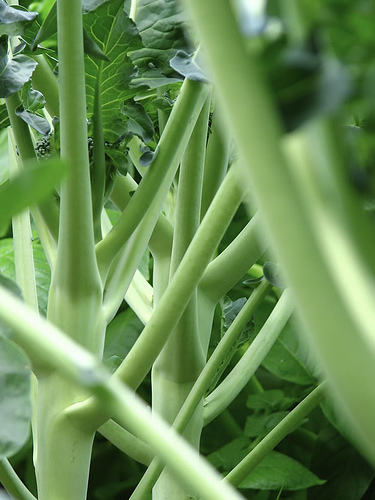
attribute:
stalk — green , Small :
[163, 90, 216, 303]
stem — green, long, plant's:
[78, 162, 246, 429]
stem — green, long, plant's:
[208, 211, 273, 299]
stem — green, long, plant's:
[0, 284, 248, 498]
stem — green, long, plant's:
[0, 93, 55, 247]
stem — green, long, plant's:
[222, 375, 332, 484]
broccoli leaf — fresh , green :
[72, 0, 140, 156]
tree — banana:
[1, 1, 372, 497]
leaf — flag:
[81, 0, 145, 145]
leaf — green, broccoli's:
[85, 13, 138, 125]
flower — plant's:
[66, 21, 289, 233]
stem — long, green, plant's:
[220, 375, 332, 494]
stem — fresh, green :
[76, 364, 244, 495]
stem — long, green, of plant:
[196, 0, 310, 167]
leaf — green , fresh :
[77, 1, 160, 154]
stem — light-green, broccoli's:
[106, 86, 213, 304]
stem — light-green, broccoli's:
[189, 50, 371, 362]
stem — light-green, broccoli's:
[5, 301, 231, 498]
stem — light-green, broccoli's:
[51, 40, 108, 301]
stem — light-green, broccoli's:
[146, 254, 221, 498]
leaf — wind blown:
[131, 50, 174, 98]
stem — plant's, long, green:
[17, 18, 327, 375]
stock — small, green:
[27, 128, 122, 190]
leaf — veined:
[73, 6, 140, 149]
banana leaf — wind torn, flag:
[88, 45, 164, 111]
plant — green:
[173, 1, 372, 469]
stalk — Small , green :
[212, 282, 305, 411]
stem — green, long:
[88, 81, 108, 240]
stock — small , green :
[175, 107, 211, 208]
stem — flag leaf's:
[89, 56, 107, 245]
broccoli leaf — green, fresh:
[82, 2, 147, 138]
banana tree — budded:
[14, 130, 129, 209]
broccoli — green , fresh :
[207, 42, 331, 258]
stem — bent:
[49, 6, 103, 346]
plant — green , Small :
[46, 121, 293, 359]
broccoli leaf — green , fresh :
[1, 3, 44, 46]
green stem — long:
[59, 8, 86, 213]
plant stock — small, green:
[186, 1, 373, 460]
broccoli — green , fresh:
[110, 205, 329, 460]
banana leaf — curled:
[13, 79, 51, 136]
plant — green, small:
[24, 42, 168, 327]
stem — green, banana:
[1, 2, 373, 499]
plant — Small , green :
[92, 96, 172, 277]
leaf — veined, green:
[0, 33, 32, 97]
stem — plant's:
[55, 1, 95, 288]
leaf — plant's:
[81, 1, 141, 240]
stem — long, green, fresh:
[32, 3, 103, 499]